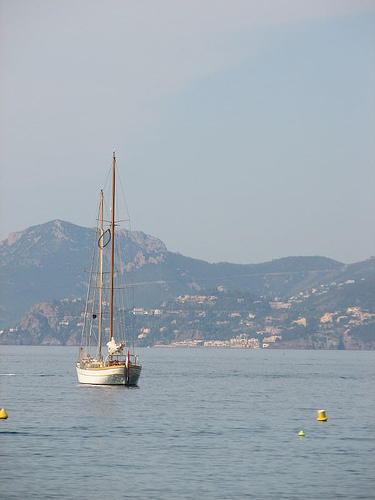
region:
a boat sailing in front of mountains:
[12, 100, 273, 478]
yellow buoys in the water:
[288, 395, 339, 447]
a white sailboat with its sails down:
[66, 145, 161, 400]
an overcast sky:
[6, 5, 364, 172]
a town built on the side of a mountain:
[12, 226, 369, 354]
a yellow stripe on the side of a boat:
[71, 357, 131, 374]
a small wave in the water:
[0, 423, 34, 442]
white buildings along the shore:
[140, 331, 280, 351]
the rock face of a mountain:
[114, 221, 172, 279]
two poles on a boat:
[87, 144, 126, 354]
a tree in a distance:
[139, 315, 144, 329]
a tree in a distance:
[192, 311, 201, 326]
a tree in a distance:
[30, 323, 36, 334]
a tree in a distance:
[58, 331, 65, 340]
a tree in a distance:
[304, 321, 313, 331]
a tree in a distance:
[250, 332, 255, 340]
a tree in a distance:
[257, 295, 263, 304]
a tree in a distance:
[216, 297, 219, 303]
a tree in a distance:
[362, 324, 369, 336]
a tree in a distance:
[303, 302, 307, 307]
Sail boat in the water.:
[69, 152, 165, 403]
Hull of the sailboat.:
[74, 364, 124, 383]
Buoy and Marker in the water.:
[296, 406, 327, 441]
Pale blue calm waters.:
[166, 356, 286, 420]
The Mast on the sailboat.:
[94, 214, 107, 340]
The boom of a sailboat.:
[106, 350, 137, 356]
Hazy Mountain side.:
[194, 217, 365, 343]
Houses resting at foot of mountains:
[128, 297, 192, 341]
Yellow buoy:
[1, 402, 10, 423]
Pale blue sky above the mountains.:
[170, 145, 355, 231]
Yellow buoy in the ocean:
[315, 406, 330, 425]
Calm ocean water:
[53, 432, 250, 479]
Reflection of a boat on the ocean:
[83, 384, 135, 423]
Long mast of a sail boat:
[107, 148, 116, 358]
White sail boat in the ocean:
[70, 363, 147, 392]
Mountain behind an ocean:
[0, 215, 172, 265]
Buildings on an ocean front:
[155, 326, 285, 351]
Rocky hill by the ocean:
[11, 292, 79, 347]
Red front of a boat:
[123, 348, 131, 385]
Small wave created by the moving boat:
[1, 370, 76, 379]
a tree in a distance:
[159, 314, 167, 328]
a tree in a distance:
[190, 306, 196, 314]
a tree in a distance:
[201, 320, 209, 326]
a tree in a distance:
[287, 325, 297, 336]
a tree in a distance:
[347, 319, 352, 324]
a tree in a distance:
[290, 324, 297, 331]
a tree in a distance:
[40, 326, 46, 332]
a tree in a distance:
[132, 317, 135, 322]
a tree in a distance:
[65, 325, 71, 330]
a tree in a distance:
[133, 317, 139, 322]